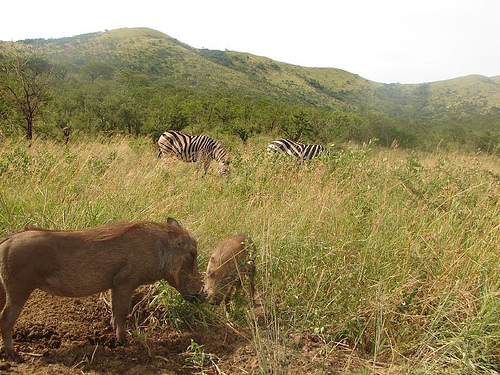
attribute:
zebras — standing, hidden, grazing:
[154, 129, 231, 176]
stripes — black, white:
[160, 133, 182, 161]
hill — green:
[6, 26, 499, 151]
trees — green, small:
[1, 47, 55, 139]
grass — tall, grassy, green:
[3, 133, 497, 374]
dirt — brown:
[0, 288, 363, 374]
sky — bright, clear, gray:
[3, 3, 498, 85]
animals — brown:
[1, 216, 205, 359]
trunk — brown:
[25, 108, 34, 144]